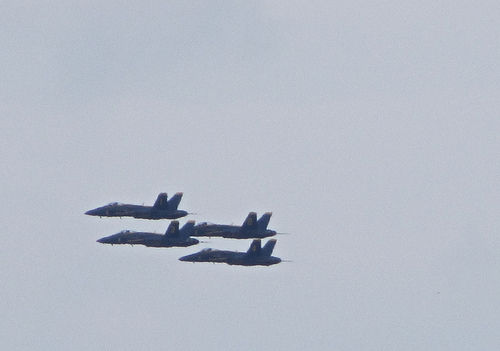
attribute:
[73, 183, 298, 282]
jets — together, flying, black, small, four, blue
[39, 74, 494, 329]
sky — cloudless, gray, grey, blue, clear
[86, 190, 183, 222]
jet — blue, flying, black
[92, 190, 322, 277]
planes — flying, formation, fighter, parallel, grouped, painted, yellow, blue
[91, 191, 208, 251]
blue angels — flying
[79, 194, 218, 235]
pilots — experienced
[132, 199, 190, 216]
wings — sharp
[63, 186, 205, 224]
plane — flying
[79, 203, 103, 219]
nose — pointed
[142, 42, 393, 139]
clouds — white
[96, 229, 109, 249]
front — sharp